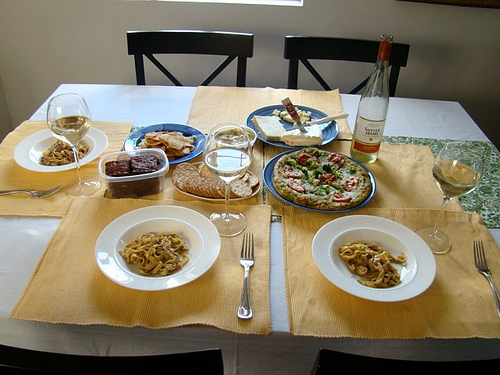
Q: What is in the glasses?
A: Wine.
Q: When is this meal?
A: Dinner.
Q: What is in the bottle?
A: Wine.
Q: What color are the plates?
A: Blue.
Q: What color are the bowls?
A: White.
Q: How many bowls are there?
A: Three.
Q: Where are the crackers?
A: On a plate.